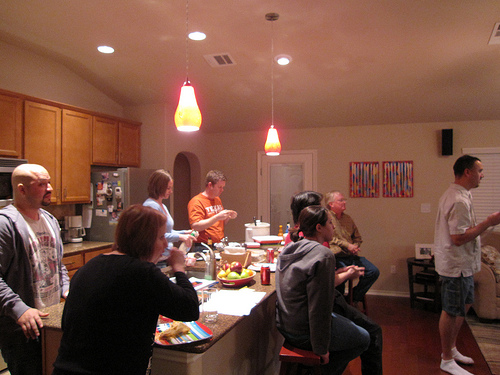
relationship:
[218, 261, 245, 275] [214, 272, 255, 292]
fruits in bowl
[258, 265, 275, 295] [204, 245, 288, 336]
can on counter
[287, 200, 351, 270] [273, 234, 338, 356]
girl wearing jacket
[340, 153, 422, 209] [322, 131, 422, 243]
paintings on wall